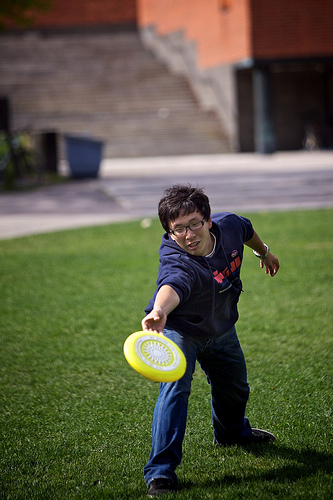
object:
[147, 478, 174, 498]
shoes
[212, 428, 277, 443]
shoes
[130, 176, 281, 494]
person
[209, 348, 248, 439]
blue jeans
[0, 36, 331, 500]
photo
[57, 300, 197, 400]
frisbee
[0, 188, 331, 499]
ground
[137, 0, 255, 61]
wall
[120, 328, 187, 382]
circle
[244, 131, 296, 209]
icon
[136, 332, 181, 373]
design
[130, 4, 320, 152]
building